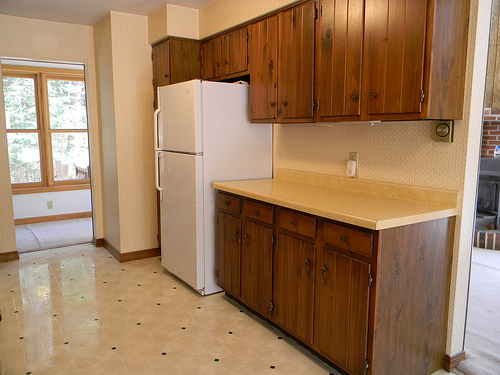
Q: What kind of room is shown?
A: It is a kitchen.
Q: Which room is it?
A: It is a kitchen.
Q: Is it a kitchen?
A: Yes, it is a kitchen.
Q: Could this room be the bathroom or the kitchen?
A: It is the kitchen.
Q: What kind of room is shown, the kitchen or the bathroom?
A: It is the kitchen.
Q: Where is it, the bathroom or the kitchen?
A: It is the kitchen.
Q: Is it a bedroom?
A: No, it is a kitchen.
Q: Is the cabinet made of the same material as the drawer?
A: Yes, both the cabinet and the drawer are made of wood.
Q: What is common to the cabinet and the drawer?
A: The material, both the cabinet and the drawer are wooden.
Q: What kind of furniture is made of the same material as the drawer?
A: The cabinet is made of the same material as the drawer.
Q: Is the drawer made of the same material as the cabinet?
A: Yes, both the drawer and the cabinet are made of wood.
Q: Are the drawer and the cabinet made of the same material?
A: Yes, both the drawer and the cabinet are made of wood.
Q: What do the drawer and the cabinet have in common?
A: The material, both the drawer and the cabinet are wooden.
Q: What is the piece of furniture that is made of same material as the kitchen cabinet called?
A: The piece of furniture is a drawer.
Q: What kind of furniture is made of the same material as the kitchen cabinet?
A: The drawer is made of the same material as the cabinet.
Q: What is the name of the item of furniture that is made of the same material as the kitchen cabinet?
A: The piece of furniture is a drawer.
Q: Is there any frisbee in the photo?
A: No, there are no frisbees.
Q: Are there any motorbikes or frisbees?
A: No, there are no frisbees or motorbikes.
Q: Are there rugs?
A: No, there are no rugs.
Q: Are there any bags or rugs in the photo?
A: No, there are no rugs or bags.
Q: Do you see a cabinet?
A: Yes, there is a cabinet.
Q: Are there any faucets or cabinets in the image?
A: Yes, there is a cabinet.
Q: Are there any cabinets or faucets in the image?
A: Yes, there is a cabinet.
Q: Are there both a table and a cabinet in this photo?
A: No, there is a cabinet but no tables.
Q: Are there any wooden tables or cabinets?
A: Yes, there is a wood cabinet.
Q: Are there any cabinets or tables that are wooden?
A: Yes, the cabinet is wooden.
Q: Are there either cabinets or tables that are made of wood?
A: Yes, the cabinet is made of wood.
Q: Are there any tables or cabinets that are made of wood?
A: Yes, the cabinet is made of wood.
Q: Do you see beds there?
A: No, there are no beds.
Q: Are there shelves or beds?
A: No, there are no beds or shelves.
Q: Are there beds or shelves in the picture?
A: No, there are no beds or shelves.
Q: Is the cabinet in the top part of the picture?
A: Yes, the cabinet is in the top of the image.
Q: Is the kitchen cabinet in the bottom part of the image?
A: No, the cabinet is in the top of the image.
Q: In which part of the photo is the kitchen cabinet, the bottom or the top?
A: The cabinet is in the top of the image.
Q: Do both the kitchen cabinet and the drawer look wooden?
A: Yes, both the cabinet and the drawer are wooden.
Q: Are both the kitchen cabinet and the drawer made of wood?
A: Yes, both the cabinet and the drawer are made of wood.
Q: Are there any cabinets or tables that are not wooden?
A: No, there is a cabinet but it is wooden.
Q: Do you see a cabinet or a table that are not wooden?
A: No, there is a cabinet but it is wooden.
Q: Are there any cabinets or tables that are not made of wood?
A: No, there is a cabinet but it is made of wood.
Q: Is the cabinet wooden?
A: Yes, the cabinet is wooden.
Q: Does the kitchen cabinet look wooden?
A: Yes, the cabinet is wooden.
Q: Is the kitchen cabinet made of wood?
A: Yes, the cabinet is made of wood.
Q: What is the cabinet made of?
A: The cabinet is made of wood.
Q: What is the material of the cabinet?
A: The cabinet is made of wood.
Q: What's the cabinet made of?
A: The cabinet is made of wood.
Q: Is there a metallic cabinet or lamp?
A: No, there is a cabinet but it is wooden.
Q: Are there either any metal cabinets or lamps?
A: No, there is a cabinet but it is wooden.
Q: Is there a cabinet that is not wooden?
A: No, there is a cabinet but it is wooden.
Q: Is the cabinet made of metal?
A: No, the cabinet is made of wood.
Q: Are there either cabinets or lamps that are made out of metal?
A: No, there is a cabinet but it is made of wood.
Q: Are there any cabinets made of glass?
A: No, there is a cabinet but it is made of wood.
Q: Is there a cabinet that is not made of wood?
A: No, there is a cabinet but it is made of wood.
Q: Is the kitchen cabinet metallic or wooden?
A: The cabinet is wooden.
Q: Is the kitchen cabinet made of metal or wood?
A: The cabinet is made of wood.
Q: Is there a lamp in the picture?
A: No, there are no lamps.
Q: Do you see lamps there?
A: No, there are no lamps.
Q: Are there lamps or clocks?
A: No, there are no lamps or clocks.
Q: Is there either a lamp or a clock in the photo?
A: No, there are no lamps or clocks.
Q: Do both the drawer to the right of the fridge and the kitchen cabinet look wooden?
A: Yes, both the drawer and the cabinet are wooden.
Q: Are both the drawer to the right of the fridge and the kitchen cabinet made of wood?
A: Yes, both the drawer and the cabinet are made of wood.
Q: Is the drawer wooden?
A: Yes, the drawer is wooden.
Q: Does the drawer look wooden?
A: Yes, the drawer is wooden.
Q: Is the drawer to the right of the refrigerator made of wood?
A: Yes, the drawer is made of wood.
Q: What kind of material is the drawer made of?
A: The drawer is made of wood.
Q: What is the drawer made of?
A: The drawer is made of wood.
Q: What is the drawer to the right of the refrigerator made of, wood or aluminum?
A: The drawer is made of wood.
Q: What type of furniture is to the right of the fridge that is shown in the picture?
A: The piece of furniture is a drawer.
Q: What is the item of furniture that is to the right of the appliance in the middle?
A: The piece of furniture is a drawer.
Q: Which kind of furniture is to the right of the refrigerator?
A: The piece of furniture is a drawer.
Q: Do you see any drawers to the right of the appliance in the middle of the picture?
A: Yes, there is a drawer to the right of the freezer.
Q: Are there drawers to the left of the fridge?
A: No, the drawer is to the right of the fridge.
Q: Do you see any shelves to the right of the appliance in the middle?
A: No, there is a drawer to the right of the fridge.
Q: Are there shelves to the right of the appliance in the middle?
A: No, there is a drawer to the right of the fridge.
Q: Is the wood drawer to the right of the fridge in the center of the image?
A: Yes, the drawer is to the right of the refrigerator.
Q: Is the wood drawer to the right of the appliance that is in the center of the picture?
A: Yes, the drawer is to the right of the refrigerator.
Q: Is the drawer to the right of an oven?
A: No, the drawer is to the right of the refrigerator.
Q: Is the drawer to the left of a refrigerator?
A: No, the drawer is to the right of a refrigerator.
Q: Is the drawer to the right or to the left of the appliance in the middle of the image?
A: The drawer is to the right of the fridge.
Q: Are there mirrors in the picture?
A: No, there are no mirrors.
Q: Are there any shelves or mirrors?
A: No, there are no mirrors or shelves.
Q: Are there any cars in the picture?
A: No, there are no cars.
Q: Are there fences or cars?
A: No, there are no cars or fences.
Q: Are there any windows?
A: Yes, there is a window.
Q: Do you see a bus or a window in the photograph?
A: Yes, there is a window.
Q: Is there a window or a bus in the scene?
A: Yes, there is a window.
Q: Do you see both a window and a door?
A: No, there is a window but no doors.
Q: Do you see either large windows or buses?
A: Yes, there is a large window.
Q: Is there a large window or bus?
A: Yes, there is a large window.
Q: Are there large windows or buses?
A: Yes, there is a large window.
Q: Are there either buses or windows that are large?
A: Yes, the window is large.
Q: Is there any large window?
A: Yes, there is a large window.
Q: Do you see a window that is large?
A: Yes, there is a window that is large.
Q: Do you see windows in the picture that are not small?
A: Yes, there is a large window.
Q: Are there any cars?
A: No, there are no cars.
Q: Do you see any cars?
A: No, there are no cars.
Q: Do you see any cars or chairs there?
A: No, there are no cars or chairs.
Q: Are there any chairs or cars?
A: No, there are no cars or chairs.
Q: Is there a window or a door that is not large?
A: No, there is a window but it is large.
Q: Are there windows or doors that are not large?
A: No, there is a window but it is large.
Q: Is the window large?
A: Yes, the window is large.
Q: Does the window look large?
A: Yes, the window is large.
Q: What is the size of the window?
A: The window is large.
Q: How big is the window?
A: The window is large.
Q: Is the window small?
A: No, the window is large.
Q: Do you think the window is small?
A: No, the window is large.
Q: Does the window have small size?
A: No, the window is large.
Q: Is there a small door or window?
A: No, there is a window but it is large.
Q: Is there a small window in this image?
A: No, there is a window but it is large.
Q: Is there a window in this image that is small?
A: No, there is a window but it is large.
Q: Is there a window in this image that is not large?
A: No, there is a window but it is large.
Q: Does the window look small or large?
A: The window is large.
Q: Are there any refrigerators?
A: Yes, there is a refrigerator.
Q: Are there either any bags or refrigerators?
A: Yes, there is a refrigerator.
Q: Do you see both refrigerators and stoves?
A: No, there is a refrigerator but no stoves.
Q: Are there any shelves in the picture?
A: No, there are no shelves.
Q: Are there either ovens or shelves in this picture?
A: No, there are no shelves or ovens.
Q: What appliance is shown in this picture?
A: The appliance is a refrigerator.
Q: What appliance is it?
A: The appliance is a refrigerator.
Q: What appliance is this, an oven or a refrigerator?
A: That is a refrigerator.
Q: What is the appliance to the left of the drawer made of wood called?
A: The appliance is a refrigerator.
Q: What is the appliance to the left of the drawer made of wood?
A: The appliance is a refrigerator.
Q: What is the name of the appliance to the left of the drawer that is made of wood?
A: The appliance is a refrigerator.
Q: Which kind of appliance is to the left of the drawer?
A: The appliance is a refrigerator.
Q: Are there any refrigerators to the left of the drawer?
A: Yes, there is a refrigerator to the left of the drawer.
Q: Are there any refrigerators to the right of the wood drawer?
A: No, the refrigerator is to the left of the drawer.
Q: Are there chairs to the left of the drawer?
A: No, there is a refrigerator to the left of the drawer.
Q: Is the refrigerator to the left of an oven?
A: No, the refrigerator is to the left of the drawer.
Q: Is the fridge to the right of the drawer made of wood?
A: No, the fridge is to the left of the drawer.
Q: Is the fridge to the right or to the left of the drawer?
A: The fridge is to the left of the drawer.